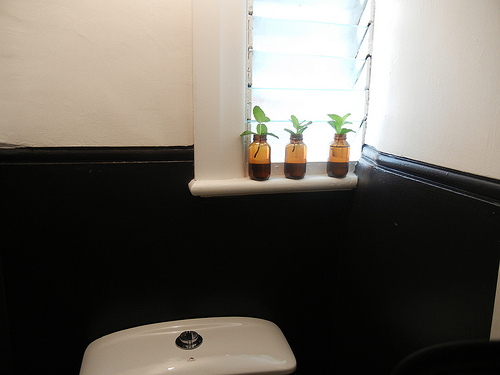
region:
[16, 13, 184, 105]
Clean unwritten grey wall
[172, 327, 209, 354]
A small shiny metal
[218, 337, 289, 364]
A crisp white surface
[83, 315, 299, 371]
Clean white toilet bowl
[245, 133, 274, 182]
Small brown bottle jar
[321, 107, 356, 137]
Green growing flower plant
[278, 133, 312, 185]
Half filled brown jar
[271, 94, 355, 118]
A clean opened window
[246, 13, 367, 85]
Pieces of sliding window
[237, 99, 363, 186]
Three identical flower jars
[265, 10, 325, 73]
glass window panes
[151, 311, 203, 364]
silver flushing toliet button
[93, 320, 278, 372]
lid of back of toliet tank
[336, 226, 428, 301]
black wall on right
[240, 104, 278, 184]
green plant in jar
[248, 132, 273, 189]
brown jar with water and plant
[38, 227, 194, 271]
black wall on left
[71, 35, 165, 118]
white wall on left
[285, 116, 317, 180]
middle plant in window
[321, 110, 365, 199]
green plant on right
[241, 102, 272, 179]
plant sitting inside brown jar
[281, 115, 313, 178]
plant sitting inside brown jar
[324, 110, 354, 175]
plant sitting inside brown jar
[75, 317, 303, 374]
white item inside sitting against wall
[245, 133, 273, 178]
brown jar sitting in window sill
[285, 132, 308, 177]
brown jar sitting in window sill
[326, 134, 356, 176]
brown jar sitting in window sill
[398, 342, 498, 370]
black item sitting in restroom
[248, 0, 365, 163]
blinds open at a window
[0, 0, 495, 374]
partially black painted restroom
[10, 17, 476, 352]
Wall is half black and half white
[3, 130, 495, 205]
Moulding between the white and black sections of wall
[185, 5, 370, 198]
Window with glass panes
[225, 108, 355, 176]
Three jars with rooting plants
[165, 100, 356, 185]
Three jars with rooting plants on window sill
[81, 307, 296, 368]
Top portion of toilet seat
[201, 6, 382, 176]
Sunlight shining through the window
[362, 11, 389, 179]
Wall bends slightly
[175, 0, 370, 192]
White moulding doesn't go all the way around the window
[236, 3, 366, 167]
Glass window panes are slightly open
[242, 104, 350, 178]
three vases of window ledge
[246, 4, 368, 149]
window in the wall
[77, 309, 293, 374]
top of white toilet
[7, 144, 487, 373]
black bottom half of wall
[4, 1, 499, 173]
white top half of wall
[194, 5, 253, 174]
white frame of the window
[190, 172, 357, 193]
white ledge of the window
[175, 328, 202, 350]
silver flush button on toilet tank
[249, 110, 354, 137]
three plants in three vases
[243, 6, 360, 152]
sunlight coming through the window